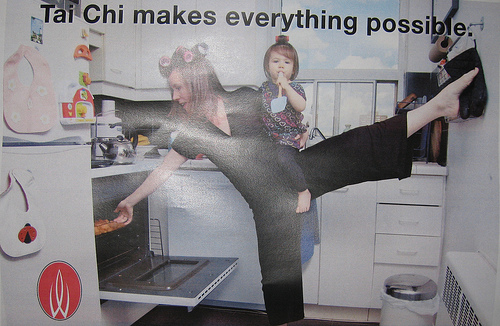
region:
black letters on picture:
[38, 0, 476, 42]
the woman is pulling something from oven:
[111, 24, 479, 324]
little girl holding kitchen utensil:
[255, 32, 321, 215]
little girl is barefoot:
[293, 186, 313, 217]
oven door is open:
[87, 173, 242, 313]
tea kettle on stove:
[95, 129, 142, 167]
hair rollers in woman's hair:
[148, 39, 210, 76]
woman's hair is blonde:
[153, 42, 228, 124]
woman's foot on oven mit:
[442, 39, 489, 124]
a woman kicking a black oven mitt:
[429, 30, 487, 119]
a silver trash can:
[378, 272, 440, 324]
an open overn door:
[96, 249, 240, 311]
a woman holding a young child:
[230, 35, 317, 200]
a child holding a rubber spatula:
[259, 43, 303, 116]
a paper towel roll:
[428, 16, 452, 61]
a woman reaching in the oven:
[94, 39, 224, 234]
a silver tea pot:
[97, 124, 144, 164]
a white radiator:
[433, 247, 498, 324]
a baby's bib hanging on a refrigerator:
[1, 42, 66, 136]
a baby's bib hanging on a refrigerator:
[3, 161, 54, 261]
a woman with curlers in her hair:
[152, 39, 228, 116]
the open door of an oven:
[86, 163, 246, 323]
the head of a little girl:
[257, 30, 301, 81]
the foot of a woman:
[433, 59, 485, 128]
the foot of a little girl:
[292, 184, 317, 219]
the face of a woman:
[168, 78, 195, 115]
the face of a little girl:
[266, 48, 294, 80]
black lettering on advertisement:
[38, 3, 469, 42]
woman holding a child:
[148, 21, 463, 323]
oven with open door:
[95, 157, 237, 310]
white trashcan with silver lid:
[380, 268, 440, 325]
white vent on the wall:
[432, 243, 492, 325]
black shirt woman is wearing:
[173, 99, 296, 193]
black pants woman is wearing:
[254, 112, 411, 317]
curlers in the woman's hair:
[156, 43, 209, 64]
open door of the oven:
[113, 239, 233, 309]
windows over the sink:
[268, 74, 391, 151]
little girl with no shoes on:
[253, 34, 312, 212]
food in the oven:
[94, 213, 124, 238]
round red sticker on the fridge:
[35, 258, 82, 321]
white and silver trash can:
[378, 271, 445, 322]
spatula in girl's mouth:
[269, 84, 289, 114]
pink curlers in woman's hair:
[158, 41, 211, 72]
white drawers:
[373, 172, 441, 268]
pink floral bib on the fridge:
[3, 44, 55, 135]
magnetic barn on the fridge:
[59, 78, 101, 126]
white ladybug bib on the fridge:
[0, 163, 46, 259]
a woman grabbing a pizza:
[76, 9, 412, 323]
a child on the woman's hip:
[214, 24, 329, 177]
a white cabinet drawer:
[379, 173, 439, 208]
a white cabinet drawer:
[380, 206, 437, 231]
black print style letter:
[36, 2, 55, 22]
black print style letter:
[49, 4, 66, 24]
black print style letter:
[63, 0, 75, 28]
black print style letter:
[81, 1, 101, 23]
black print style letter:
[102, 1, 118, 27]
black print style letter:
[130, 6, 157, 24]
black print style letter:
[154, 6, 168, 26]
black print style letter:
[170, 3, 184, 27]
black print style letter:
[187, 5, 202, 25]